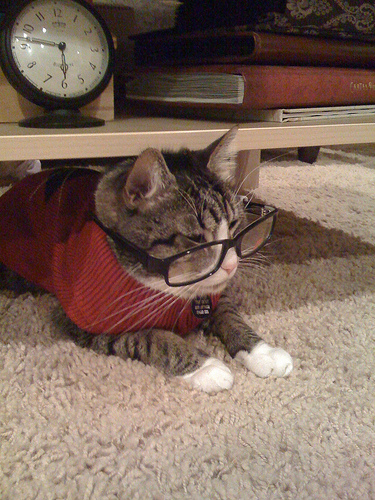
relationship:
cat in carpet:
[2, 118, 295, 391] [1, 140, 361, 492]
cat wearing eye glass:
[2, 118, 295, 391] [101, 195, 281, 291]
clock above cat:
[1, 2, 120, 128] [2, 118, 295, 391]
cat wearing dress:
[2, 118, 295, 391] [2, 166, 217, 337]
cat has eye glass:
[2, 118, 295, 391] [101, 195, 281, 291]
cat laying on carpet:
[2, 118, 295, 391] [1, 140, 361, 492]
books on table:
[129, 8, 374, 126] [2, 119, 374, 168]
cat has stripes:
[2, 118, 295, 391] [174, 157, 231, 223]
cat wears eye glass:
[2, 118, 295, 391] [101, 195, 281, 291]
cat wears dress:
[2, 118, 295, 391] [2, 166, 217, 337]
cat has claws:
[2, 118, 295, 391] [184, 341, 300, 392]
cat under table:
[2, 118, 295, 391] [2, 119, 374, 168]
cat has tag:
[2, 118, 295, 391] [183, 293, 221, 319]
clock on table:
[1, 2, 120, 128] [2, 119, 374, 168]